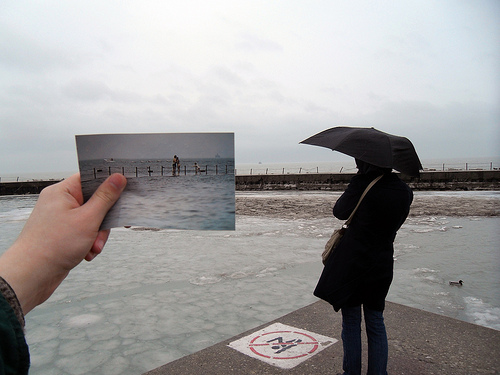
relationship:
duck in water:
[453, 267, 465, 290] [215, 163, 329, 245]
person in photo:
[166, 153, 183, 178] [50, 125, 235, 242]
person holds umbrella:
[321, 172, 406, 373] [328, 133, 431, 197]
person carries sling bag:
[310, 152, 414, 372] [322, 172, 387, 258]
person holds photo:
[1, 181, 125, 374] [50, 125, 235, 242]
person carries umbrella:
[310, 152, 414, 372] [328, 133, 431, 197]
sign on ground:
[216, 309, 325, 359] [192, 273, 499, 368]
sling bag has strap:
[322, 172, 387, 258] [342, 175, 378, 233]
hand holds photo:
[9, 176, 133, 302] [50, 125, 235, 242]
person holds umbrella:
[310, 152, 414, 372] [328, 133, 431, 197]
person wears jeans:
[310, 152, 414, 372] [310, 310, 429, 370]